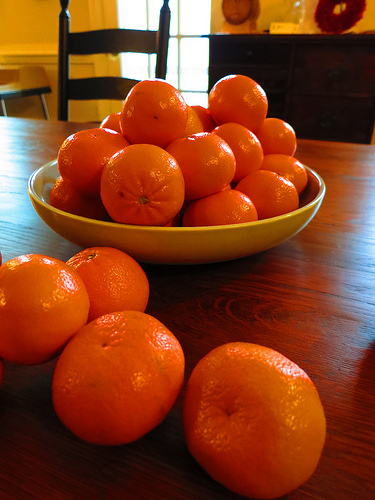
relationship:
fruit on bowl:
[98, 140, 185, 224] [28, 157, 327, 264]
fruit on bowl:
[51, 75, 308, 224] [28, 157, 327, 264]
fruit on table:
[178, 339, 334, 499] [329, 133, 367, 216]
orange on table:
[0, 243, 327, 500] [1, 137, 373, 498]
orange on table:
[1, 250, 96, 376] [1, 137, 373, 498]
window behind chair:
[117, 6, 209, 99] [49, 0, 178, 124]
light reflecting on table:
[1, 118, 43, 258] [292, 147, 374, 410]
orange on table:
[0, 243, 327, 500] [1, 117, 100, 264]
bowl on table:
[28, 157, 327, 264] [341, 185, 372, 253]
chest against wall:
[180, 14, 373, 133] [209, 1, 363, 33]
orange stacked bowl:
[170, 132, 242, 193] [171, 218, 266, 275]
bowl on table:
[13, 154, 334, 280] [330, 140, 372, 498]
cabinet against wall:
[209, 23, 374, 144] [2, 0, 55, 48]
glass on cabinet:
[274, 1, 319, 25] [295, 34, 373, 143]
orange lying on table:
[0, 243, 327, 500] [1, 137, 373, 498]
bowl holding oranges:
[28, 157, 327, 264] [45, 73, 308, 196]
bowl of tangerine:
[28, 157, 327, 264] [99, 143, 183, 223]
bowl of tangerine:
[28, 157, 327, 264] [56, 127, 125, 196]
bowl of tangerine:
[28, 157, 327, 264] [119, 80, 187, 147]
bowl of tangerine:
[28, 157, 327, 264] [166, 132, 237, 198]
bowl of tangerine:
[28, 157, 327, 264] [207, 73, 267, 132]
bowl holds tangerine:
[28, 157, 327, 264] [204, 70, 268, 133]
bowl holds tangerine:
[28, 157, 327, 264] [118, 72, 189, 150]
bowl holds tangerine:
[28, 157, 327, 264] [207, 119, 266, 183]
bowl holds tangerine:
[28, 157, 327, 264] [250, 114, 297, 161]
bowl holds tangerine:
[28, 157, 327, 264] [96, 141, 187, 227]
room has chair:
[2, 1, 362, 212] [57, 0, 173, 122]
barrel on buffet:
[217, 0, 267, 31] [186, 15, 361, 56]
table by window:
[2, 65, 51, 117] [116, 0, 210, 107]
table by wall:
[0, 67, 53, 115] [0, 2, 123, 118]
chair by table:
[0, 113, 372, 498] [5, 116, 350, 476]